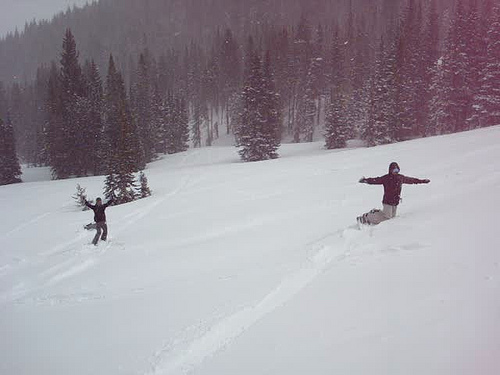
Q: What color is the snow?
A: White.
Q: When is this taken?
A: During the day.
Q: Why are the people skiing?
A: For fun.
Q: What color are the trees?
A: Green.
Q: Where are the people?
A: In the snow.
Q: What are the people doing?
A: Skiing.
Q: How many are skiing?
A: Two.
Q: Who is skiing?
A: The two women.